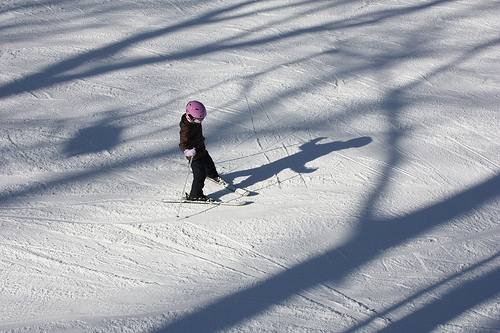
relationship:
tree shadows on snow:
[3, 0, 498, 330] [310, 87, 425, 189]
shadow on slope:
[60, 120, 130, 166] [19, 31, 151, 292]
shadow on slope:
[238, 130, 376, 201] [4, 8, 477, 329]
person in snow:
[178, 99, 232, 203] [5, 207, 497, 329]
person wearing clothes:
[178, 99, 232, 203] [173, 111, 223, 191]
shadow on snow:
[299, 104, 394, 196] [366, 76, 460, 228]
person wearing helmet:
[137, 102, 242, 210] [177, 87, 214, 124]